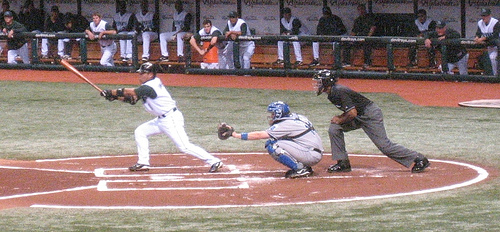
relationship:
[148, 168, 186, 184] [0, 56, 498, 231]
plate on field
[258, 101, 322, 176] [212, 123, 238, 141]
catcher with glove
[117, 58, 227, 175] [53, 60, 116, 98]
player swings bat.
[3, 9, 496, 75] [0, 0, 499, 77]
players in dugout.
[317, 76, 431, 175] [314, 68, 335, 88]
umpire wearing helmet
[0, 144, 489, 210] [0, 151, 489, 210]
lines of lines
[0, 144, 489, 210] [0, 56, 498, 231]
lines on field.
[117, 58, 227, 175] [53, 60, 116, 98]
player with bat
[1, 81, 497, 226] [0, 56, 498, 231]
grass on field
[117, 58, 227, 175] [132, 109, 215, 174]
player wearing pants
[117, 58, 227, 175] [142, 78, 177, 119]
player wearing jersey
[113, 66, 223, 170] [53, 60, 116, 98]
batter holds bat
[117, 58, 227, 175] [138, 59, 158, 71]
player wears helmet.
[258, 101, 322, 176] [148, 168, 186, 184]
catcher behind plate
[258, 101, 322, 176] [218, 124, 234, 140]
catcher has glove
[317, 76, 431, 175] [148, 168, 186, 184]
umpire behind plate.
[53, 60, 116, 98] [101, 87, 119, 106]
bat in hands.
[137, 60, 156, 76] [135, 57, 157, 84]
helmet on head.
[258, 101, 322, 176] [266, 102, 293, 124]
catcher wearing mask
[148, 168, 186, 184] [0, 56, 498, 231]
plate on field.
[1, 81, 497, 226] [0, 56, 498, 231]
grass on field.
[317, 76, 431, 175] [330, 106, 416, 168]
man wearing pants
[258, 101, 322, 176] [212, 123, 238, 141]
player has mitt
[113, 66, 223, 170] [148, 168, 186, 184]
batter at plate.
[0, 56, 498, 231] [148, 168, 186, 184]
field. has plate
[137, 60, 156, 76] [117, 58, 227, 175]
helmet on player.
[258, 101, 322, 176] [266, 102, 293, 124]
catcher wearing mask.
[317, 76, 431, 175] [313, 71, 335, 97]
umpire wears mask.